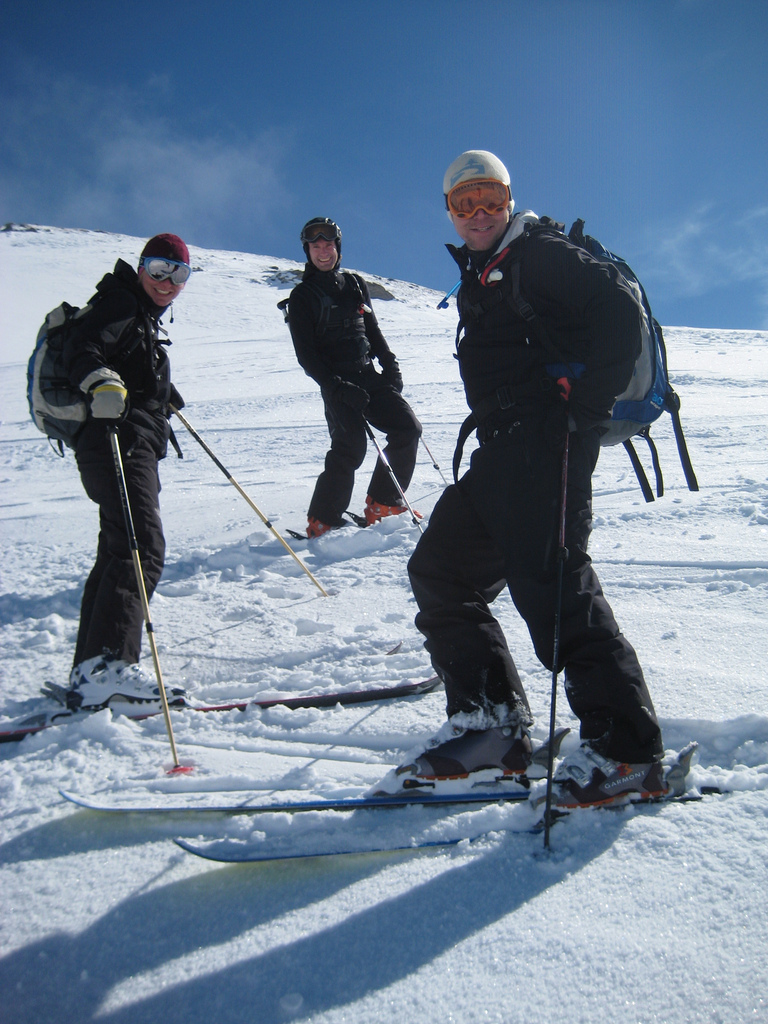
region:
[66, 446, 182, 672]
Man wearing pants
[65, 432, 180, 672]
Man is wearing pants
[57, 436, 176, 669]
Man wearing black pants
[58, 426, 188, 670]
Man is wearing black pants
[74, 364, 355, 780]
Man holding ski poles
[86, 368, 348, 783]
Man is holding ski poles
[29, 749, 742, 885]
Man is on skis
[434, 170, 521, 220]
Man wearing orange ski goggles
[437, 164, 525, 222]
Man is wearing orange ski goggles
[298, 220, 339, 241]
the goggles are black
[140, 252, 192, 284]
the goggles are blue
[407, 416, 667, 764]
the pants are black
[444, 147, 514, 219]
the hat is white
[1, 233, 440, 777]
the man is wearing ski gear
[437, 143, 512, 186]
man is wearing a white hat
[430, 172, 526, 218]
yellow and black sunglasses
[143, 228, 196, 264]
man is wearing a red hat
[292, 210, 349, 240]
man is wearing a black helmet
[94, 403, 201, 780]
man is holding a ski stick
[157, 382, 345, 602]
man is holding a ski stick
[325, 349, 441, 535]
man is holding a ski stick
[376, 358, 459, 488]
man is holding a ski stick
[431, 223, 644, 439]
man is wearing a black jacket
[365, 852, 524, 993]
white snow on the ground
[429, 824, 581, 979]
snow covering the ground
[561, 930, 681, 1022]
white snow covering the ground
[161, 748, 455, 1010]
a shadow on the snow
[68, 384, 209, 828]
a person holding a ski pole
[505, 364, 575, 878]
a person holding a ski pole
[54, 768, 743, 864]
Pair of skis covered with snow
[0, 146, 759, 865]
Skiers in the slope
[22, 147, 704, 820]
Three skiers with backpack on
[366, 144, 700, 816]
Skier with orange goggles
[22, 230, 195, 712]
Skier with blue goggles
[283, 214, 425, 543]
Skier with black goggles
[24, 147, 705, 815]
Three happy skiers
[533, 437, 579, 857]
Long skinny ski pole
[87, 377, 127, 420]
Gray and yellow glove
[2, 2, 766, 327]
Dark blue sky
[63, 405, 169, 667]
the black ski pants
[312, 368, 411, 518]
the black ski pants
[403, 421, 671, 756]
the black ski pants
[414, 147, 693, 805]
A person is standing up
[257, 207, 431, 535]
A person is standing up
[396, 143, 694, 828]
A person is standing up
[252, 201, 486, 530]
A person is standing up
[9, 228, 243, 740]
A person is standing up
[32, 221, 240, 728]
A person on some snow.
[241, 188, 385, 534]
A person on some snow.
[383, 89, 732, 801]
A person on some snow.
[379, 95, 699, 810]
A person on some skis.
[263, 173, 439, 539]
A person on some skis.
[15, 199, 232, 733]
A person on some skis.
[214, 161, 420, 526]
A person on some skis.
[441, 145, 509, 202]
gray balaclava snowboarder is wearing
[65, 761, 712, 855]
blue and white snowboard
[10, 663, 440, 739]
black and red snowboard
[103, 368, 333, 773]
yellow poles of person wearing red balaclava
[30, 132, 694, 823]
three snowboarders standing together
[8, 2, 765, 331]
light blue clear sky